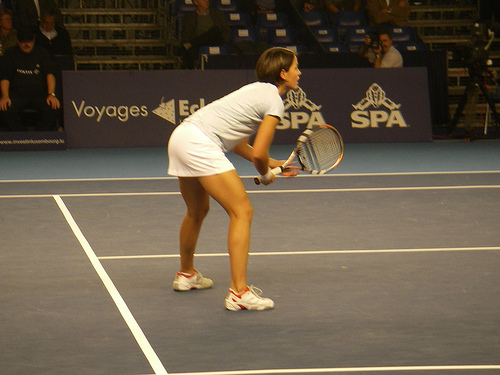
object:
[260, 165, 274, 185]
hand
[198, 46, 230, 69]
empty chair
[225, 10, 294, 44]
group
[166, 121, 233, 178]
white skirt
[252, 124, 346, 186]
racket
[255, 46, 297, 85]
hair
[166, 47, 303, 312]
woman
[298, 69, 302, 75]
nose